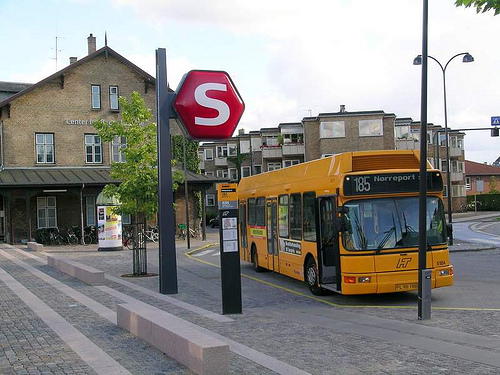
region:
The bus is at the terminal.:
[197, 110, 459, 306]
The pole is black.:
[132, 23, 183, 303]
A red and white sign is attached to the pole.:
[171, 58, 256, 151]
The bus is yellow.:
[230, 132, 451, 302]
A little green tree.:
[85, 80, 165, 282]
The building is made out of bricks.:
[27, 100, 82, 116]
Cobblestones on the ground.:
[7, 330, 42, 372]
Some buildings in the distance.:
[198, 105, 414, 176]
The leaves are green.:
[447, 0, 492, 23]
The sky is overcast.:
[232, 20, 392, 63]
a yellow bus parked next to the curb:
[196, 130, 470, 337]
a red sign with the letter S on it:
[136, 37, 250, 311]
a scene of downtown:
[22, 17, 492, 372]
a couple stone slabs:
[42, 237, 246, 372]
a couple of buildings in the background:
[5, 35, 499, 247]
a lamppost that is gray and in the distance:
[406, 32, 480, 259]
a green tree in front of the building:
[79, 87, 197, 294]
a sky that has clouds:
[3, 10, 497, 157]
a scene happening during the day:
[16, 11, 488, 366]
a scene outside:
[17, 7, 482, 368]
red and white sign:
[165, 41, 290, 149]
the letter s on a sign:
[175, 75, 250, 150]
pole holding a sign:
[140, 145, 195, 245]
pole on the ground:
[365, 66, 470, 271]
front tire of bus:
[285, 250, 330, 305]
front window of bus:
[332, 190, 427, 275]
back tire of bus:
[241, 235, 268, 277]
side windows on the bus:
[225, 192, 330, 242]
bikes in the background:
[41, 224, 107, 251]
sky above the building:
[271, 11, 336, 68]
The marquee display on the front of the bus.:
[344, 175, 441, 195]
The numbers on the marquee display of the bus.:
[351, 173, 377, 191]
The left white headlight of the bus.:
[360, 270, 374, 285]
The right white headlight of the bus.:
[437, 270, 449, 275]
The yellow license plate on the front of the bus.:
[394, 283, 421, 290]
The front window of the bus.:
[348, 197, 446, 254]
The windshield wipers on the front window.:
[363, 215, 434, 254]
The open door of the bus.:
[319, 193, 341, 290]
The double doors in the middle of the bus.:
[256, 196, 283, 268]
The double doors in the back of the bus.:
[232, 200, 251, 262]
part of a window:
[356, 212, 406, 248]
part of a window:
[326, 189, 365, 241]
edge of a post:
[211, 241, 221, 266]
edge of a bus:
[334, 238, 354, 266]